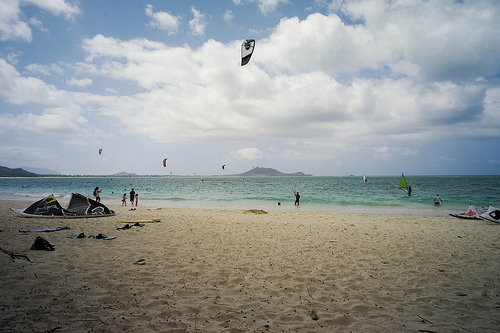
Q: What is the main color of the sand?
A: Brown.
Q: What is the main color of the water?
A: Blue.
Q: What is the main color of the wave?
A: Blue.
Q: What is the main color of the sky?
A: Blue.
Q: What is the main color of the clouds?
A: White.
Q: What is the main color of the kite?
A: White.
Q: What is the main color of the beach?
A: Brown.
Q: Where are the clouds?
A: In the sky.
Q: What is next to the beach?
A: The ocean.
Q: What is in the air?
A: A kite.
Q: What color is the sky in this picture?
A: Blue.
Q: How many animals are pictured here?
A: Zero.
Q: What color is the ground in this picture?
A: Tan.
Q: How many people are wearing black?
A: Two.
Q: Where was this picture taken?
A: A Beach.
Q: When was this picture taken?
A: Daytime.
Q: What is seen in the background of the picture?
A: A Mountain.